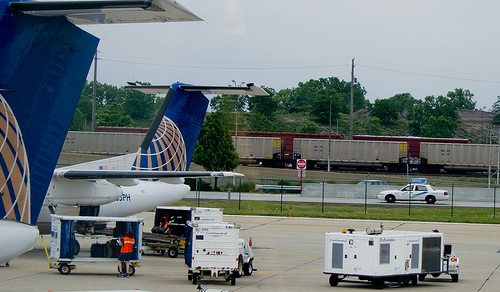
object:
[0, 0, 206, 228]
tail-fin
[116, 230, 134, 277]
luggage handler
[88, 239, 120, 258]
luggage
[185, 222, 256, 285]
truck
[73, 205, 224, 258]
truck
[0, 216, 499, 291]
tarmac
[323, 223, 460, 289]
truck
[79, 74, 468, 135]
tree foliage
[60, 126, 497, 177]
freight train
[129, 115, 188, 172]
globe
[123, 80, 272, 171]
plane tail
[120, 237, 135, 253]
vest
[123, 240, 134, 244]
stripe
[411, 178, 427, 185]
sign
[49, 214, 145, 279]
cart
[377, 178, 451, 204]
car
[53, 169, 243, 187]
right wing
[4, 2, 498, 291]
airport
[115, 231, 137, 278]
man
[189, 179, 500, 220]
fence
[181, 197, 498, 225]
grass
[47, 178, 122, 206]
engine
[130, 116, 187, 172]
logo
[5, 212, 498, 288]
airport runway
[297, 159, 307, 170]
sign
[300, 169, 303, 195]
pole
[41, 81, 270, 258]
airplane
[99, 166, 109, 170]
american flag